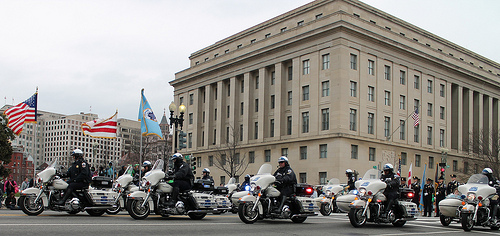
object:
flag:
[138, 87, 164, 140]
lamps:
[178, 104, 187, 113]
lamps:
[169, 101, 177, 112]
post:
[169, 120, 181, 157]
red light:
[407, 192, 414, 198]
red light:
[305, 187, 314, 193]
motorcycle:
[237, 162, 318, 225]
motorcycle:
[436, 172, 499, 227]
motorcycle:
[345, 168, 419, 228]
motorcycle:
[318, 178, 360, 216]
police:
[340, 168, 359, 191]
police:
[470, 167, 498, 225]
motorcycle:
[125, 159, 218, 219]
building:
[165, 0, 499, 204]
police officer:
[198, 165, 215, 187]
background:
[0, 0, 486, 233]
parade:
[20, 146, 500, 232]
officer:
[163, 153, 202, 207]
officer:
[52, 148, 94, 206]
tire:
[347, 206, 368, 228]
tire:
[126, 195, 150, 220]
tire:
[17, 194, 46, 217]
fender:
[349, 200, 371, 220]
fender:
[238, 195, 264, 216]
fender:
[126, 190, 154, 210]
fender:
[19, 187, 50, 209]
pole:
[30, 83, 40, 183]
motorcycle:
[16, 156, 123, 217]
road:
[0, 206, 500, 236]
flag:
[80, 110, 117, 139]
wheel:
[238, 196, 261, 225]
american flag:
[4, 92, 38, 136]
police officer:
[380, 163, 403, 218]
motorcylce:
[106, 164, 143, 215]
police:
[269, 155, 298, 214]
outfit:
[271, 166, 297, 210]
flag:
[1, 93, 35, 136]